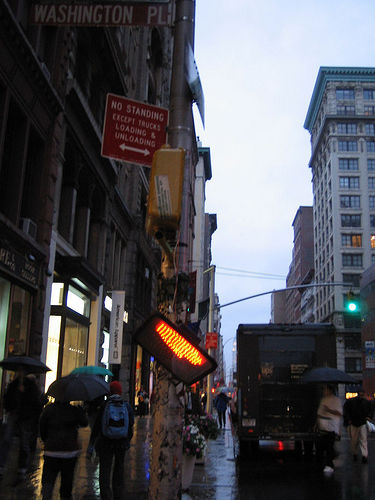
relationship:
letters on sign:
[113, 101, 162, 147] [100, 90, 167, 169]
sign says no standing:
[100, 90, 167, 169] [111, 99, 171, 124]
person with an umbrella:
[33, 398, 89, 499] [49, 374, 109, 402]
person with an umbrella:
[84, 385, 105, 459] [71, 364, 118, 378]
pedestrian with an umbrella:
[314, 380, 343, 478] [302, 362, 357, 394]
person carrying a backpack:
[91, 379, 136, 500] [100, 401, 132, 441]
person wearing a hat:
[91, 379, 136, 500] [108, 378, 124, 395]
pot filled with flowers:
[183, 448, 202, 499] [182, 424, 206, 456]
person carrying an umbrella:
[33, 398, 89, 499] [49, 374, 109, 402]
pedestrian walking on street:
[314, 380, 343, 478] [208, 388, 374, 499]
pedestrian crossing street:
[314, 380, 343, 478] [208, 388, 374, 499]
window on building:
[338, 153, 360, 172] [303, 61, 374, 438]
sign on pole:
[100, 90, 167, 169] [153, 0, 199, 500]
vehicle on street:
[235, 322, 339, 471] [208, 388, 374, 499]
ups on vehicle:
[258, 357, 279, 375] [235, 322, 339, 471]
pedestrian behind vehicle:
[314, 380, 343, 478] [235, 322, 339, 471]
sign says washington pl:
[28, 4, 192, 36] [34, 4, 171, 23]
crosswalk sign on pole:
[139, 319, 219, 388] [153, 0, 199, 500]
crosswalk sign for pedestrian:
[139, 319, 219, 388] [302, 384, 374, 484]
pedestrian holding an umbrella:
[314, 380, 343, 478] [302, 362, 357, 394]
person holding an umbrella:
[33, 398, 89, 499] [49, 374, 109, 402]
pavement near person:
[13, 450, 133, 499] [33, 398, 89, 499]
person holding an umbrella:
[84, 385, 105, 459] [71, 364, 118, 378]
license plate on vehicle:
[240, 417, 258, 430] [235, 322, 339, 471]